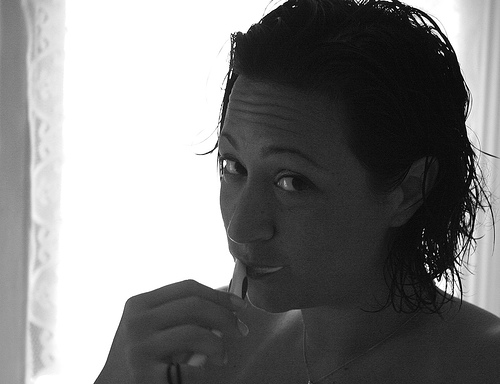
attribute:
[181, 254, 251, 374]
toothbrush — white, grey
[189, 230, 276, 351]
toothbrush — black, white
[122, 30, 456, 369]
girl — holding